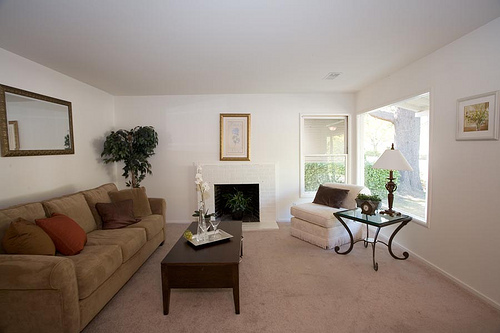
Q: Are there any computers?
A: No, there are no computers.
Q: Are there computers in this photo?
A: No, there are no computers.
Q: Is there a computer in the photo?
A: No, there are no computers.